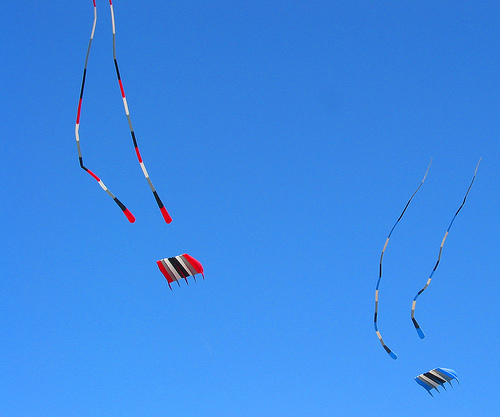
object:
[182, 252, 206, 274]
stripe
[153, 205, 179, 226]
red stripe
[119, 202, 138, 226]
red stripe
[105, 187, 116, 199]
gray stripe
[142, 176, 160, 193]
gray stripe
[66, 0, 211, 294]
kite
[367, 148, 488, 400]
kite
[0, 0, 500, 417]
blue sky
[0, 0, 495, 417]
sky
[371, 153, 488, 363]
tail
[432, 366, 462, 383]
stripes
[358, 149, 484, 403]
kites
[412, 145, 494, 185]
tips